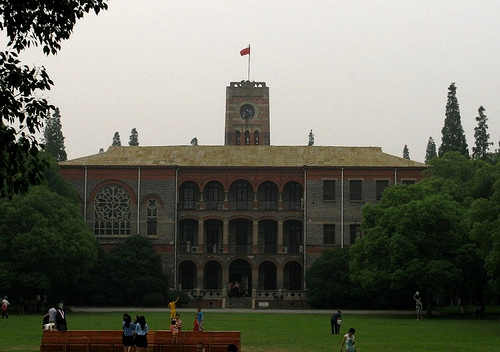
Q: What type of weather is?
A: It is clear.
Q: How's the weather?
A: It is clear.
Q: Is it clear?
A: Yes, it is clear.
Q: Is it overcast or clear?
A: It is clear.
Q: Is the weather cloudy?
A: No, it is clear.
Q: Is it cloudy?
A: No, it is clear.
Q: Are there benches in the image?
A: Yes, there is a bench.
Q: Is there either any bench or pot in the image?
A: Yes, there is a bench.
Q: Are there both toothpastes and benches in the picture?
A: No, there is a bench but no toothpastes.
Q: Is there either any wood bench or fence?
A: Yes, there is a wood bench.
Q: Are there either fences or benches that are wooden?
A: Yes, the bench is wooden.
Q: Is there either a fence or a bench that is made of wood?
A: Yes, the bench is made of wood.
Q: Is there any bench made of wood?
A: Yes, there is a bench that is made of wood.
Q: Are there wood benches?
A: Yes, there is a bench that is made of wood.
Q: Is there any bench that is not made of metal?
A: Yes, there is a bench that is made of wood.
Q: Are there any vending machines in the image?
A: No, there are no vending machines.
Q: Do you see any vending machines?
A: No, there are no vending machines.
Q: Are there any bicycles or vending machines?
A: No, there are no vending machines or bicycles.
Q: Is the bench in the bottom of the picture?
A: Yes, the bench is in the bottom of the image.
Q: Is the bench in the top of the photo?
A: No, the bench is in the bottom of the image.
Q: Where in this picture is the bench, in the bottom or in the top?
A: The bench is in the bottom of the image.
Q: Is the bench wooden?
A: Yes, the bench is wooden.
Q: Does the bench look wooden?
A: Yes, the bench is wooden.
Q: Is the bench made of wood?
A: Yes, the bench is made of wood.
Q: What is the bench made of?
A: The bench is made of wood.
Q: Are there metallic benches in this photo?
A: No, there is a bench but it is wooden.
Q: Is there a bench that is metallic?
A: No, there is a bench but it is wooden.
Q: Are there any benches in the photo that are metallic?
A: No, there is a bench but it is wooden.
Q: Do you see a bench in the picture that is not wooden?
A: No, there is a bench but it is wooden.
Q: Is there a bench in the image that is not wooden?
A: No, there is a bench but it is wooden.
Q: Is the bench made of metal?
A: No, the bench is made of wood.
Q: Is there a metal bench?
A: No, there is a bench but it is made of wood.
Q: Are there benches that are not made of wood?
A: No, there is a bench but it is made of wood.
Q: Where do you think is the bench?
A: The bench is on the grass.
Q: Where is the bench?
A: The bench is on the grass.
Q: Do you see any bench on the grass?
A: Yes, there is a bench on the grass.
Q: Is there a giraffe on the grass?
A: No, there is a bench on the grass.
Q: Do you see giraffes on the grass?
A: No, there is a bench on the grass.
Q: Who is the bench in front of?
A: The bench is in front of the girl.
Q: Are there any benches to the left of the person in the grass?
A: Yes, there is a bench to the left of the person.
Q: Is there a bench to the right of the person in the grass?
A: No, the bench is to the left of the person.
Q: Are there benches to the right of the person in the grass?
A: No, the bench is to the left of the person.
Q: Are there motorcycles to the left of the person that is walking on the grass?
A: No, there is a bench to the left of the person.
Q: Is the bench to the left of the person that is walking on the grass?
A: Yes, the bench is to the left of the person.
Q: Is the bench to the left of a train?
A: No, the bench is to the left of the person.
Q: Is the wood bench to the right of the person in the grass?
A: No, the bench is to the left of the person.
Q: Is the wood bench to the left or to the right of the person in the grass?
A: The bench is to the left of the person.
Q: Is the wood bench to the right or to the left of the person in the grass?
A: The bench is to the left of the person.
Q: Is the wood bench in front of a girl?
A: Yes, the bench is in front of a girl.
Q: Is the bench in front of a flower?
A: No, the bench is in front of a girl.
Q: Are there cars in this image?
A: No, there are no cars.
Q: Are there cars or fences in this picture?
A: No, there are no cars or fences.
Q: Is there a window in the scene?
A: Yes, there is a window.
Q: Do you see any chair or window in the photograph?
A: Yes, there is a window.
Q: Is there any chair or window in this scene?
A: Yes, there is a window.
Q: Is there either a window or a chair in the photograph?
A: Yes, there is a window.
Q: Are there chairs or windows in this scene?
A: Yes, there is a window.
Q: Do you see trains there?
A: No, there are no trains.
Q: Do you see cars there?
A: No, there are no cars.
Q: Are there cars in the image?
A: No, there are no cars.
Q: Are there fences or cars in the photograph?
A: No, there are no cars or fences.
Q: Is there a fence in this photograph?
A: No, there are no fences.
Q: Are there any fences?
A: No, there are no fences.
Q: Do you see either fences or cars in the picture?
A: No, there are no fences or cars.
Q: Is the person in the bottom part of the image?
A: Yes, the person is in the bottom of the image.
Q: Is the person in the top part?
A: No, the person is in the bottom of the image.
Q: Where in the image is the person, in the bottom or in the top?
A: The person is in the bottom of the image.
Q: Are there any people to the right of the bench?
A: Yes, there is a person to the right of the bench.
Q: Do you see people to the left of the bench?
A: No, the person is to the right of the bench.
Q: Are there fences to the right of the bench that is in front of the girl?
A: No, there is a person to the right of the bench.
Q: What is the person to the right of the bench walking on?
A: The person is walking on the grass.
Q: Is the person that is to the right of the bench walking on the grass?
A: Yes, the person is walking on the grass.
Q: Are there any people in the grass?
A: Yes, there is a person in the grass.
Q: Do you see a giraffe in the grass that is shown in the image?
A: No, there is a person in the grass.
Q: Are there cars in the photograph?
A: No, there are no cars.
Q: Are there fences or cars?
A: No, there are no cars or fences.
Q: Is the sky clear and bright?
A: Yes, the sky is clear and bright.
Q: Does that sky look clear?
A: Yes, the sky is clear.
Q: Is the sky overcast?
A: No, the sky is clear.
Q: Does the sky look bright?
A: Yes, the sky is bright.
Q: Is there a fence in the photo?
A: No, there are no fences.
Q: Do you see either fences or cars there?
A: No, there are no fences or cars.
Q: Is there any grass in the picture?
A: Yes, there is grass.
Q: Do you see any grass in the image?
A: Yes, there is grass.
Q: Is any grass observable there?
A: Yes, there is grass.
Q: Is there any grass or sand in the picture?
A: Yes, there is grass.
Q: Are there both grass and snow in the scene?
A: No, there is grass but no snow.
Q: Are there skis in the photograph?
A: No, there are no skis.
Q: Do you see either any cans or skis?
A: No, there are no skis or cans.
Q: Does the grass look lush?
A: Yes, the grass is lush.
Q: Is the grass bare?
A: No, the grass is lush.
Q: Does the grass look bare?
A: No, the grass is lush.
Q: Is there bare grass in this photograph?
A: No, there is grass but it is lush.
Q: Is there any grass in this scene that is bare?
A: No, there is grass but it is lush.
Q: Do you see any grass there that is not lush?
A: No, there is grass but it is lush.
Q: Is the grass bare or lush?
A: The grass is lush.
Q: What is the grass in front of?
A: The grass is in front of the building.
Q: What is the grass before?
A: The grass is in front of the building.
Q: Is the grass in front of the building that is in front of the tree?
A: Yes, the grass is in front of the building.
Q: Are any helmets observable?
A: No, there are no helmets.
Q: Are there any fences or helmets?
A: No, there are no helmets or fences.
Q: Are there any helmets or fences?
A: No, there are no helmets or fences.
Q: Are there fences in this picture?
A: No, there are no fences.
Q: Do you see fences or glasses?
A: No, there are no fences or glasses.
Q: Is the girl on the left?
A: Yes, the girl is on the left of the image.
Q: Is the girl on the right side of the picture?
A: No, the girl is on the left of the image.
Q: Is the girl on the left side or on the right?
A: The girl is on the left of the image.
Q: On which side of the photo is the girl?
A: The girl is on the left of the image.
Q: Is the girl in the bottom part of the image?
A: Yes, the girl is in the bottom of the image.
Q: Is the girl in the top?
A: No, the girl is in the bottom of the image.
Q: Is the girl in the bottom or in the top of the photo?
A: The girl is in the bottom of the image.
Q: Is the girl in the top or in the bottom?
A: The girl is in the bottom of the image.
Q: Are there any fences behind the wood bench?
A: No, there is a girl behind the bench.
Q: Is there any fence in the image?
A: No, there are no fences.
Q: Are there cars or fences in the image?
A: No, there are no fences or cars.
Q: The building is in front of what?
A: The building is in front of the tree.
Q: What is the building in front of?
A: The building is in front of the tree.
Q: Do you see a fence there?
A: No, there are no fences.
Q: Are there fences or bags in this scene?
A: No, there are no fences or bags.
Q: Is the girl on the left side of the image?
A: Yes, the girl is on the left of the image.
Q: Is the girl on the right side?
A: No, the girl is on the left of the image.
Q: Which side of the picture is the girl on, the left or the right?
A: The girl is on the left of the image.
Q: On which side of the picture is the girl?
A: The girl is on the left of the image.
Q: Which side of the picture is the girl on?
A: The girl is on the left of the image.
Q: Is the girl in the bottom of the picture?
A: Yes, the girl is in the bottom of the image.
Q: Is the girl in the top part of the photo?
A: No, the girl is in the bottom of the image.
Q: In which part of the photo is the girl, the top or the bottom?
A: The girl is in the bottom of the image.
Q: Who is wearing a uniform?
A: The girl is wearing a uniform.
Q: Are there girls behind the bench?
A: Yes, there is a girl behind the bench.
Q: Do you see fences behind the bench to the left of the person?
A: No, there is a girl behind the bench.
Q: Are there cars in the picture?
A: No, there are no cars.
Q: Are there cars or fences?
A: No, there are no cars or fences.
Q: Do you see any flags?
A: Yes, there is a flag.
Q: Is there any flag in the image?
A: Yes, there is a flag.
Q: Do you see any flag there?
A: Yes, there is a flag.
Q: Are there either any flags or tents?
A: Yes, there is a flag.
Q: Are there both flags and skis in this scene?
A: No, there is a flag but no skis.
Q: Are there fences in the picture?
A: No, there are no fences.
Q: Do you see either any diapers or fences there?
A: No, there are no fences or diapers.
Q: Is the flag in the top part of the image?
A: Yes, the flag is in the top of the image.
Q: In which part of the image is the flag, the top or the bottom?
A: The flag is in the top of the image.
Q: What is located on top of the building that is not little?
A: The flag is on top of the building.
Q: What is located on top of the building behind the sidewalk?
A: The flag is on top of the building.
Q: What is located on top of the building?
A: The flag is on top of the building.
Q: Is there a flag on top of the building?
A: Yes, there is a flag on top of the building.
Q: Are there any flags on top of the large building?
A: Yes, there is a flag on top of the building.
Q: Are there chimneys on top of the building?
A: No, there is a flag on top of the building.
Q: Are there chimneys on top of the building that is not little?
A: No, there is a flag on top of the building.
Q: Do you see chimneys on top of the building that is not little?
A: No, there is a flag on top of the building.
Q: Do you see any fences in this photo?
A: No, there are no fences.